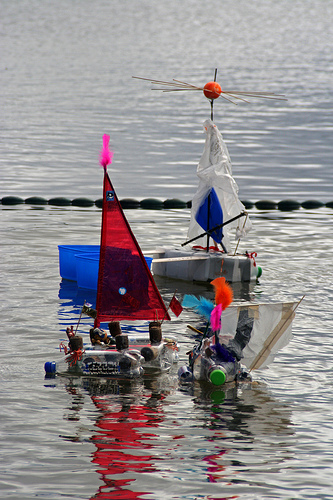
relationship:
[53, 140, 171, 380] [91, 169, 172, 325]
boat has sail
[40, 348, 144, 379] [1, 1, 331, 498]
bottle in water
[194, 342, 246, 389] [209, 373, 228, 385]
bottle has cap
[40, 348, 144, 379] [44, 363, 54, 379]
bottle has cap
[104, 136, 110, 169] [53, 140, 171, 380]
feather on boat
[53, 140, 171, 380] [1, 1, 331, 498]
boat in water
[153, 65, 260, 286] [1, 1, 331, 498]
boat in water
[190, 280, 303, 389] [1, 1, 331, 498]
boat in water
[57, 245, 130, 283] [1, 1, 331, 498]
tub in water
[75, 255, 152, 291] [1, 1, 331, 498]
tub in water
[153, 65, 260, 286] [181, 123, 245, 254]
boat has sail